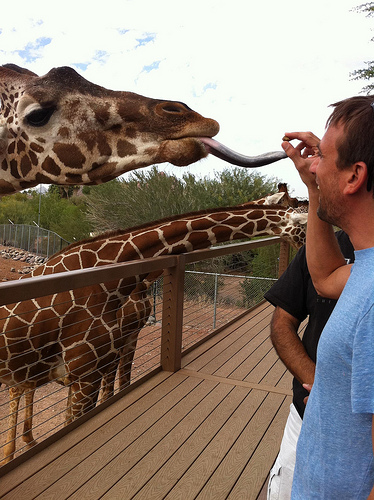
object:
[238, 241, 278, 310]
tree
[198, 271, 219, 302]
tree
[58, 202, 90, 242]
tree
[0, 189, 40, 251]
tree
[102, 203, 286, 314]
neck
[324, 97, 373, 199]
brown hair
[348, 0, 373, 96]
leaves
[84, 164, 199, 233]
tree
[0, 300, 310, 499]
deck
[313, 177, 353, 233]
facial hair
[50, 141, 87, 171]
spots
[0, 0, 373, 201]
sky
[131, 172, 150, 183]
leaves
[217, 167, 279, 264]
tree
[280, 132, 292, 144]
food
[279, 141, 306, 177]
fingers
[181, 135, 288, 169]
tongue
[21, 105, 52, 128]
eye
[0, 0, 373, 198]
white cloud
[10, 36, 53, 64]
blue sky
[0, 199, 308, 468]
giraffe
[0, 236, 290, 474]
fence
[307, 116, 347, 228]
face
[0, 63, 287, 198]
giraffe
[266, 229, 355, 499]
guy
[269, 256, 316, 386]
arm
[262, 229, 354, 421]
shirt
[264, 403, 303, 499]
pants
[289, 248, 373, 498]
blue shirt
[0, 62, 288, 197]
head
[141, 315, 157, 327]
rocks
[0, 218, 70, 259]
fence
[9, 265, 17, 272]
rocks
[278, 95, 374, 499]
guy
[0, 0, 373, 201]
clouds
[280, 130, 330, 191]
hand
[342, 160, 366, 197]
ear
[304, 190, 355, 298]
arm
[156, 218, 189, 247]
spots